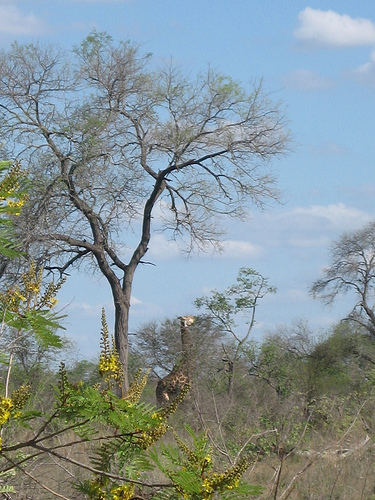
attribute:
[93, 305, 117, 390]
flowers — golden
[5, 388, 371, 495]
bushes — branched, dead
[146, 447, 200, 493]
leaf — green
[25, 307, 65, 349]
leaf — green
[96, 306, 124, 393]
flower — yellow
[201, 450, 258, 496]
flower — yellow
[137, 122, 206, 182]
branch — OF A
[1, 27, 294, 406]
tree — tall, sparsly leafed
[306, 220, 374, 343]
tree — tall, sparsly leafed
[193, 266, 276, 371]
tree — tall, sparsly leafed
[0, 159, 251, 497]
tree — tall, sparsly leafed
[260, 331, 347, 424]
tree — tall, sparsly leafed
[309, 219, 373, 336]
tree — bare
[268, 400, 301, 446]
grass — brown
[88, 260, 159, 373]
trunk — thin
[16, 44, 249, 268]
tree — bare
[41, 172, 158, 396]
tree — HAS A